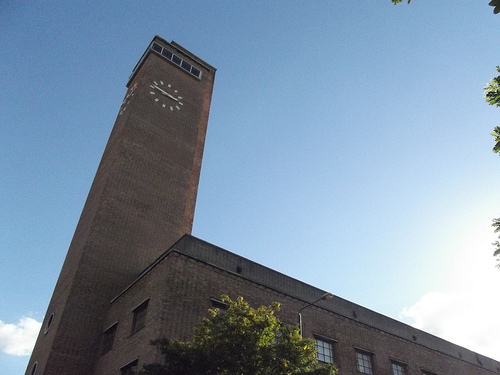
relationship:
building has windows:
[100, 235, 500, 374] [315, 335, 336, 367]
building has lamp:
[100, 235, 500, 374] [299, 292, 336, 315]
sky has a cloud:
[218, 1, 487, 246] [1, 317, 35, 359]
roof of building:
[177, 232, 208, 256] [100, 235, 500, 374]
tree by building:
[485, 1, 499, 263] [100, 235, 500, 374]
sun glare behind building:
[411, 197, 500, 335] [100, 235, 500, 374]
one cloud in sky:
[1, 317, 35, 359] [218, 1, 487, 246]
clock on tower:
[147, 78, 186, 114] [75, 32, 218, 234]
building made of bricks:
[100, 235, 500, 374] [161, 262, 202, 334]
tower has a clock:
[75, 32, 218, 234] [147, 78, 186, 114]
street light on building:
[299, 292, 336, 315] [100, 235, 500, 374]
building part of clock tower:
[100, 235, 500, 374] [75, 32, 218, 234]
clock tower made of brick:
[75, 32, 218, 234] [84, 208, 149, 269]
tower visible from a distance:
[75, 32, 218, 234] [22, 32, 500, 374]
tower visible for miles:
[24, 32, 217, 373] [0, 1, 499, 374]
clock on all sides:
[147, 78, 186, 114] [113, 82, 139, 118]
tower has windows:
[24, 32, 217, 373] [153, 44, 205, 81]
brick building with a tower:
[100, 235, 500, 374] [24, 32, 217, 373]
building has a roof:
[100, 235, 500, 374] [177, 232, 499, 370]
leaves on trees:
[231, 304, 309, 364] [144, 292, 339, 375]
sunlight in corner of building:
[416, 186, 499, 325] [66, 41, 473, 364]